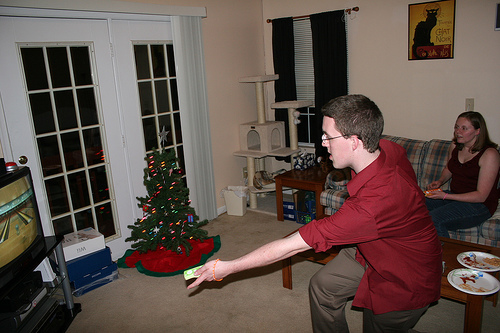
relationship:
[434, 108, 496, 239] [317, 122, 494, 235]
woman on couch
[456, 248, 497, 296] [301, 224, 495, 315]
plates on table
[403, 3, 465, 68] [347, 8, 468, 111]
drawing on wall